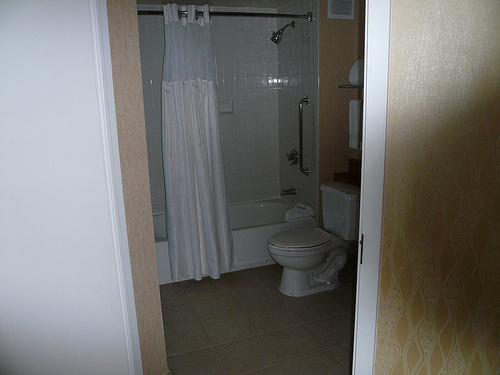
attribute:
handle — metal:
[287, 90, 322, 177]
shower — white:
[146, 20, 316, 208]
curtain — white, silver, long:
[166, 22, 223, 221]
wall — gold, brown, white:
[324, 34, 359, 62]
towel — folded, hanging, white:
[341, 101, 365, 149]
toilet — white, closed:
[272, 234, 347, 291]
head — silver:
[269, 22, 291, 45]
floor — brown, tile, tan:
[211, 288, 265, 327]